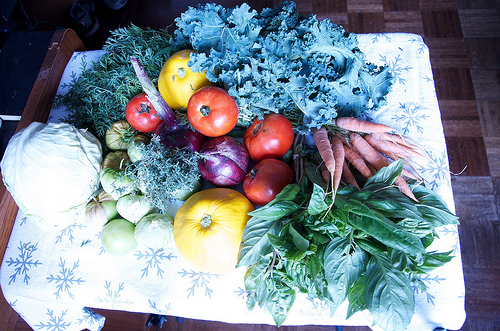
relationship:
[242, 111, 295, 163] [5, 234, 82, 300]
tomato on table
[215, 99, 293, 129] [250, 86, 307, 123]
group of green kale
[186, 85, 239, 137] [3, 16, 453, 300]
tomato on mat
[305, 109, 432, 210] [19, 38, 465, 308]
carrots on mat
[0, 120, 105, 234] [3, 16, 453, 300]
cabbage on mat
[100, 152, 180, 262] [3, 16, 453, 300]
tomatillos on mat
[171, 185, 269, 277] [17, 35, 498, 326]
squash on mat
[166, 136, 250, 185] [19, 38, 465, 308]
onions on mat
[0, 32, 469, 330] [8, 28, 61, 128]
tablecloth on object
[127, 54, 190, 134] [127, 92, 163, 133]
vegetable next to tomato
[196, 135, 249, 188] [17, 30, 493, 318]
onions on table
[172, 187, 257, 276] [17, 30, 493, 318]
squash on table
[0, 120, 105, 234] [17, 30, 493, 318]
cabbage on end of table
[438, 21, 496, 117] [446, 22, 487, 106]
squares on floor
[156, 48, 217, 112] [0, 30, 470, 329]
vegetable on table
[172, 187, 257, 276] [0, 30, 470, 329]
squash on table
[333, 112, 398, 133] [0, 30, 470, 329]
carrot on table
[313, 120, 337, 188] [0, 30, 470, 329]
carrot on table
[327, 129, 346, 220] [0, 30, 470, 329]
carrot on table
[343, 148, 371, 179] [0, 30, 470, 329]
carrot on table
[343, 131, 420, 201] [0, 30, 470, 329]
carrot on table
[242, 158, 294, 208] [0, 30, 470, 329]
tomato on table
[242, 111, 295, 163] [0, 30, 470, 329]
tomato on table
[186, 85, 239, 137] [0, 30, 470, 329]
tomato on table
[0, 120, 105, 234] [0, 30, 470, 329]
cabbage on table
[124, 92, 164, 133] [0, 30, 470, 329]
tomato on table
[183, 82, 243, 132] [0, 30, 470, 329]
tomato on table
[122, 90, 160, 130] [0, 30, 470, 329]
tomato on table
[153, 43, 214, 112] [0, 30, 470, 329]
vegetable on table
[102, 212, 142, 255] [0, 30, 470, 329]
vegetable on table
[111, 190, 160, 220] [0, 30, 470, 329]
vegetable on table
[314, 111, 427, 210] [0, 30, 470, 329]
carrots on table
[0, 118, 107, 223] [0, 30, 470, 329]
cabbage on table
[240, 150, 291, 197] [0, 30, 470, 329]
tomato on table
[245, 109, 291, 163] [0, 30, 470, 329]
tomato on table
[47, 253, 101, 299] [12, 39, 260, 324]
snowflakes on tablecloth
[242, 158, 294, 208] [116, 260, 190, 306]
tomato on table